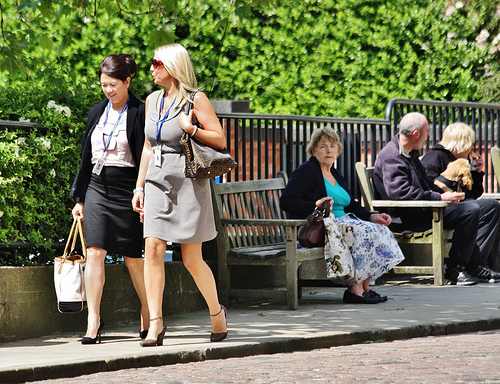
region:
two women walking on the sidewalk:
[50, 43, 235, 345]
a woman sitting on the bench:
[282, 125, 404, 302]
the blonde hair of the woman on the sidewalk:
[153, 40, 203, 110]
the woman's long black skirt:
[83, 164, 145, 257]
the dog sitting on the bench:
[437, 158, 472, 205]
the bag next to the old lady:
[299, 200, 331, 244]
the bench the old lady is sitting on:
[208, 169, 363, 307]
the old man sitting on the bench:
[375, 109, 499, 286]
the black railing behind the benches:
[215, 99, 499, 211]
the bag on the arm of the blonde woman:
[184, 91, 237, 177]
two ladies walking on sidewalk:
[7, 35, 264, 381]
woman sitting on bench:
[220, 122, 412, 315]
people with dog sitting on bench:
[362, 107, 499, 304]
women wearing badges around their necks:
[60, 50, 244, 352]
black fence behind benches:
[239, 86, 459, 231]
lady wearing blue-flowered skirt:
[260, 113, 407, 308]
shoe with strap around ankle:
[112, 294, 258, 359]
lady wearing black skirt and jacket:
[64, 57, 148, 292]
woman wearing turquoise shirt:
[267, 120, 386, 238]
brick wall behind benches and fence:
[212, 81, 399, 241]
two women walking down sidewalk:
[22, 29, 269, 364]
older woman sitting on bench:
[208, 122, 410, 309]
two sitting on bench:
[365, 105, 499, 287]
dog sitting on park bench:
[418, 151, 475, 217]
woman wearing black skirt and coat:
[57, 48, 157, 338]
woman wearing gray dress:
[128, 35, 232, 339]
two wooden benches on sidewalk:
[200, 153, 499, 298]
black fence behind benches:
[45, 70, 496, 267]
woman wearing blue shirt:
[278, 122, 410, 304]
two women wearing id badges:
[64, 33, 238, 346]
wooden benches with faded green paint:
[213, 161, 498, 313]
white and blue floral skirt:
[320, 214, 405, 286]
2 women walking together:
[43, 42, 240, 348]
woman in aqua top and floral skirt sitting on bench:
[205, 126, 415, 308]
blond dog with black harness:
[432, 158, 479, 207]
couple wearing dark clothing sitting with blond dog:
[354, 114, 498, 287]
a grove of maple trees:
[1, 0, 497, 263]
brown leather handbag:
[298, 209, 330, 251]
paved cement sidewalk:
[0, 276, 499, 377]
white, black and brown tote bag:
[52, 219, 87, 315]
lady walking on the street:
[136, 42, 228, 351]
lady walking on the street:
[45, 46, 160, 349]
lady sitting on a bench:
[276, 123, 405, 308]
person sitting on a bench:
[375, 103, 499, 286]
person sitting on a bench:
[417, 114, 490, 208]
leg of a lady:
[136, 180, 171, 347]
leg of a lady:
[175, 203, 237, 343]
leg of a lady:
[75, 189, 117, 348]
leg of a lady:
[109, 198, 160, 341]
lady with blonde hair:
[120, 38, 241, 351]